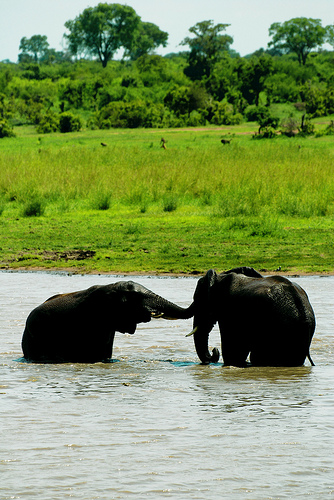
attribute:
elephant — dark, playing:
[187, 267, 321, 369]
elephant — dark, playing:
[20, 279, 192, 364]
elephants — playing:
[20, 266, 316, 366]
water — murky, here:
[3, 270, 333, 500]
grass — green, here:
[4, 125, 334, 277]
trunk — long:
[194, 315, 220, 366]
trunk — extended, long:
[152, 292, 196, 321]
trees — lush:
[3, 2, 334, 99]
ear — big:
[196, 268, 219, 305]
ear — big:
[101, 288, 137, 335]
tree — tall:
[62, 2, 168, 67]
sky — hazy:
[3, 0, 334, 64]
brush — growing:
[5, 186, 333, 282]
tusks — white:
[147, 305, 198, 339]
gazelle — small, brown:
[98, 136, 171, 149]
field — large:
[0, 114, 333, 273]